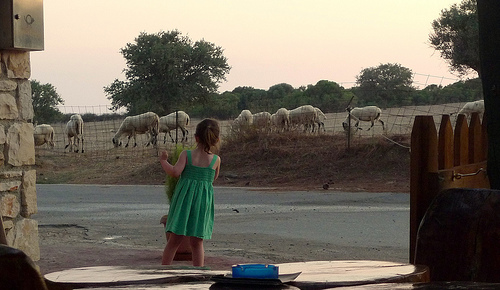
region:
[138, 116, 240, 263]
Little girl wearing a green dress.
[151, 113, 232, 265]
Little girl watching the animals.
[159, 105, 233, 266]
Little girl named Sally.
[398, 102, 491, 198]
Wood gate at the entrance.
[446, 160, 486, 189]
Silver handle on the gate.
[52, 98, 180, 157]
Fence to keep the animals inside.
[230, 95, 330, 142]
Herd of animals in the field.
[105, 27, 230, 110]
Large tree in the field.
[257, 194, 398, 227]
Paved road beside the field.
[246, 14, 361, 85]
Sun is setting over the tree line.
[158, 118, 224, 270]
A little girl in a green dress.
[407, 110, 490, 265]
Brown wood fence gate with a silver latch.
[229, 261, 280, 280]
A blue ashtray on a table.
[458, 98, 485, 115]
A white sheep with no visible head above a fence gate.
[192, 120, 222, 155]
Brown hair on a little girl in a green dress.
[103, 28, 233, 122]
A large dark green tree straight to the left of a girl.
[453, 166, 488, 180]
Silver hook on a wood gate.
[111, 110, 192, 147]
Two white sheep grazing to the left of a little girls head.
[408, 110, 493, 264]
A brown wooden gate to the right of a little girl.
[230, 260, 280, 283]
A blue ashtray sitting on a table.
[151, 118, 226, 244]
A little girl watching the goats.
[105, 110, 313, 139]
Goats behind the fence.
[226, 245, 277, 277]
A blue ashtray on the table.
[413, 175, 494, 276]
A dirty looking chair at the table.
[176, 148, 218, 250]
The girl is wearing a green dress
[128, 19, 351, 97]
Trees in the field.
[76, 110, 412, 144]
A gate on the hill.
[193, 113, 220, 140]
The girl hair is in a ponytail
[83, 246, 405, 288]
A round brown table.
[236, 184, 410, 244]
The street has water on it.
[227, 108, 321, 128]
the sheep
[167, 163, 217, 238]
a girl wearing a dress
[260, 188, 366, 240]
the street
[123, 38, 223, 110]
a green tree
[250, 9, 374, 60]
the sky is clear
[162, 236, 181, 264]
the girls leg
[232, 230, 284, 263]
dirt on the ground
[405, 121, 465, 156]
a wooden fence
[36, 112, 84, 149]
two sheep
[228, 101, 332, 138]
the sheep are white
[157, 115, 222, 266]
a little girl in a green sundress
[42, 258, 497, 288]
table pulled together behind the girl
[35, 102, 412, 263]
a young girl watching a flock of animals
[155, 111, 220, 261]
a girl standing behind a green plant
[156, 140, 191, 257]
a green plant in a pink flower pot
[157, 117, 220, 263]
a little girl standing behind a plant in a pink pot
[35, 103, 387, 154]
a flock of white animals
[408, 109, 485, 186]
the top of a wooden gate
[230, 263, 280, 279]
a blue ashtray on a wooden table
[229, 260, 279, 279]
a blue cigarette tray